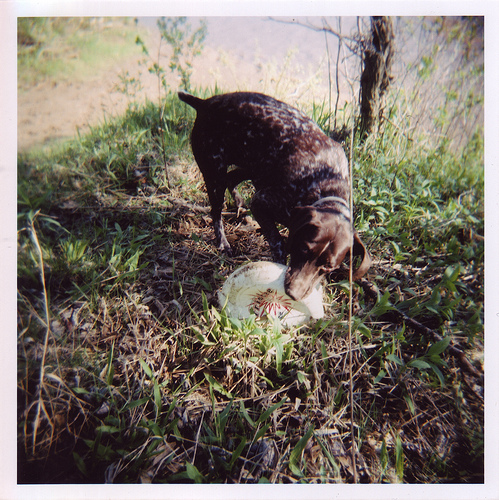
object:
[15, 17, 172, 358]
outside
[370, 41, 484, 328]
outside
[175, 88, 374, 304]
dog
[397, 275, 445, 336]
grass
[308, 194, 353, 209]
collar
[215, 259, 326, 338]
frisbee